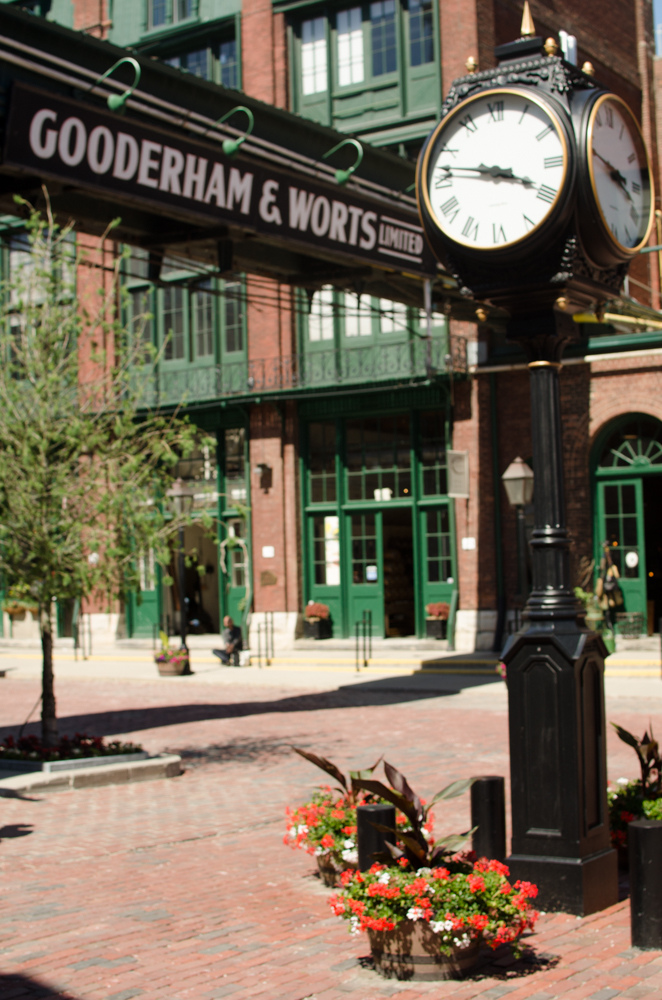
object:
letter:
[59, 117, 86, 166]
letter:
[137, 140, 162, 188]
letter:
[159, 146, 185, 195]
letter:
[204, 163, 225, 208]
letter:
[226, 168, 253, 216]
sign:
[29, 108, 424, 263]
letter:
[259, 178, 282, 226]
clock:
[413, 31, 654, 919]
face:
[421, 86, 570, 251]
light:
[107, 92, 125, 107]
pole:
[88, 57, 140, 99]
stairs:
[115, 642, 456, 671]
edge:
[78, 662, 458, 667]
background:
[0, 0, 662, 672]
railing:
[119, 331, 467, 416]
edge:
[84, 374, 464, 412]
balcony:
[114, 332, 453, 417]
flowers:
[325, 852, 537, 978]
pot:
[367, 922, 483, 982]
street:
[2, 684, 662, 803]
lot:
[278, 743, 538, 981]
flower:
[340, 868, 355, 886]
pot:
[315, 852, 365, 889]